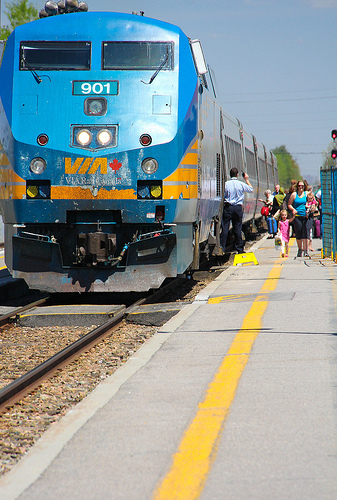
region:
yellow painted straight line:
[181, 329, 263, 497]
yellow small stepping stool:
[223, 242, 262, 276]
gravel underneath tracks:
[37, 363, 87, 418]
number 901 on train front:
[58, 65, 172, 131]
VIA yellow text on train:
[58, 149, 134, 184]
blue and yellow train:
[41, 30, 290, 194]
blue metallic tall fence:
[309, 151, 335, 258]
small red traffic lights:
[328, 126, 335, 145]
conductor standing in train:
[219, 134, 255, 239]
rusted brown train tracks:
[23, 289, 97, 367]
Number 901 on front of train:
[68, 76, 139, 103]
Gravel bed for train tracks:
[1, 290, 157, 482]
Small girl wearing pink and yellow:
[275, 208, 296, 260]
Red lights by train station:
[328, 128, 336, 162]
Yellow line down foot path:
[145, 226, 308, 495]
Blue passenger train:
[6, 2, 287, 250]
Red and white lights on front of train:
[14, 114, 170, 179]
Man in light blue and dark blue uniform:
[221, 165, 259, 254]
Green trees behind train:
[269, 141, 305, 192]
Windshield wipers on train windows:
[14, 35, 174, 89]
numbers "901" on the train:
[71, 80, 122, 94]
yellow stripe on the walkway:
[173, 270, 287, 498]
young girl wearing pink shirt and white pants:
[278, 208, 291, 256]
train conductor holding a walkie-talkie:
[214, 164, 252, 253]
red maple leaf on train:
[110, 155, 122, 176]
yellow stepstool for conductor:
[230, 251, 259, 270]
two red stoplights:
[324, 128, 335, 164]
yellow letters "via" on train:
[59, 155, 109, 179]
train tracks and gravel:
[0, 311, 111, 395]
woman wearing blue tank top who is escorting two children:
[276, 178, 321, 268]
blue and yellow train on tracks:
[10, 12, 253, 342]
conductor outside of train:
[201, 154, 280, 283]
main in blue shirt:
[206, 157, 272, 275]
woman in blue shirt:
[287, 173, 324, 268]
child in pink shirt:
[257, 170, 298, 273]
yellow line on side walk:
[194, 190, 260, 498]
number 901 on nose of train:
[51, 59, 130, 113]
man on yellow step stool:
[226, 161, 272, 274]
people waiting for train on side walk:
[259, 157, 320, 275]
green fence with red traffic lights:
[303, 122, 335, 273]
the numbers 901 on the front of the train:
[63, 76, 127, 99]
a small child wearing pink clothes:
[270, 204, 299, 262]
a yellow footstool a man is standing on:
[223, 244, 261, 273]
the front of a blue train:
[8, 10, 186, 317]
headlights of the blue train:
[68, 122, 119, 150]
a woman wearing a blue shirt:
[286, 176, 322, 251]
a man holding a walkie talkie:
[215, 159, 250, 261]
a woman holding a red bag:
[257, 184, 275, 221]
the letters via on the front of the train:
[52, 150, 119, 181]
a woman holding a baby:
[282, 170, 322, 264]